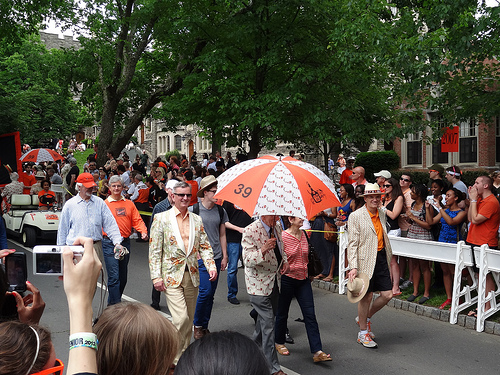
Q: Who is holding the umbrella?
A: A man.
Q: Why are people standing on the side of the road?
A: They are watching the parade.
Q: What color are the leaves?
A: Green.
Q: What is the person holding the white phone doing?
A: Taking a picture.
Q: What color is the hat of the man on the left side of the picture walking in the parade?
A: Orange.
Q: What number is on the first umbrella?
A: 39.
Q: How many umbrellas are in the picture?
A: 2.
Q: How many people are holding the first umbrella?
A: 1.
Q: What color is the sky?
A: White.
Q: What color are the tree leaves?
A: Green.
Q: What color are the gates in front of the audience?
A: White.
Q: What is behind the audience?
A: Homes.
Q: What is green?
A: Trees.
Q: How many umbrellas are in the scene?
A: Two.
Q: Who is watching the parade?
A: Spectators.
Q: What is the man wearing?
A: A suit jacket and dress slacks.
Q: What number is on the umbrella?
A: 39.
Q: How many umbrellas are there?
A: 2.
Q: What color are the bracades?
A: White.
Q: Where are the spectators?
A: Behind the barricades.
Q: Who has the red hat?
A: The man wearing the blue shirt.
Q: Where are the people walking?
A: On the pavement.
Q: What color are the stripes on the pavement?
A: White.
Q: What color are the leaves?
A: Green.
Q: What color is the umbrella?
A: Orange and white.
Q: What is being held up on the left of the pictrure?
A: A camera.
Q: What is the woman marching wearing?
A: Blue jeans.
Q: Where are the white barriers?
A: In front of the spectators.